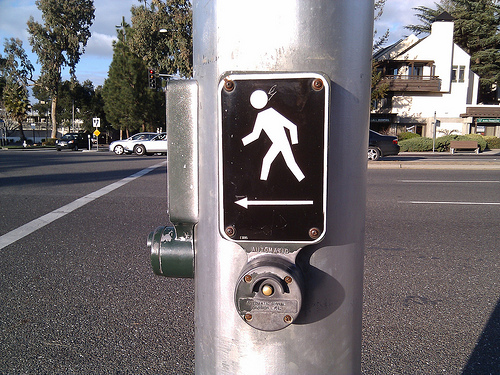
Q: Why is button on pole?
A: Control crossing light.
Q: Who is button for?
A: Pedestrians.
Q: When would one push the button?
A: To cross the street.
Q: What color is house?
A: White.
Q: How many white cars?
A: Two.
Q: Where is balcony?
A: On white house.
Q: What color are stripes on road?
A: White.